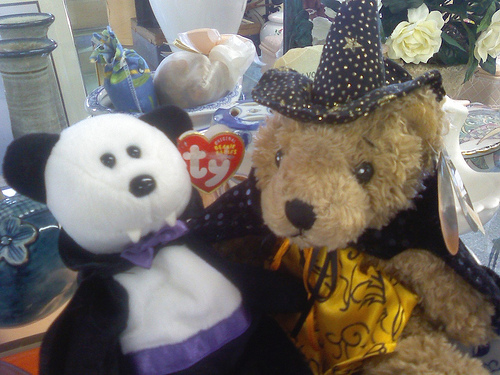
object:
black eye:
[350, 160, 374, 186]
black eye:
[273, 150, 280, 166]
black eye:
[128, 146, 139, 157]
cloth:
[227, 226, 418, 360]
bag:
[88, 22, 162, 114]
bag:
[152, 24, 259, 111]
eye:
[351, 161, 375, 183]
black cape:
[37, 220, 309, 374]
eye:
[98, 151, 123, 172]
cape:
[179, 166, 499, 333]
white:
[44, 112, 244, 355]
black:
[1, 130, 69, 203]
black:
[35, 234, 139, 375]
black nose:
[282, 197, 318, 232]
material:
[263, 235, 423, 373]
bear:
[184, 0, 496, 374]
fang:
[163, 210, 178, 227]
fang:
[126, 226, 143, 243]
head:
[242, 85, 445, 250]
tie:
[118, 218, 200, 268]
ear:
[1, 131, 59, 205]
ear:
[139, 103, 191, 143]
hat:
[250, 1, 447, 125]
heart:
[174, 131, 247, 194]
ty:
[183, 143, 231, 185]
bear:
[0, 105, 324, 374]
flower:
[381, 2, 447, 65]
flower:
[470, 11, 500, 73]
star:
[342, 34, 364, 54]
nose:
[281, 196, 317, 230]